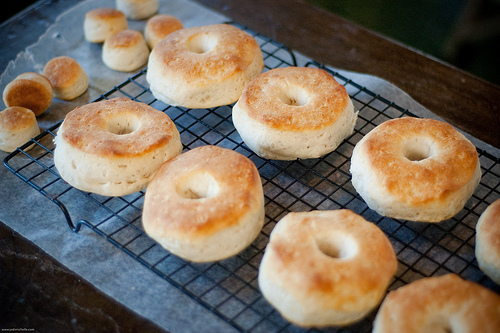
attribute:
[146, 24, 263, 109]
biscuit — brown, plain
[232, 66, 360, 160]
biscuit — brown, plain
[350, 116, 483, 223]
biscuit — brown, plain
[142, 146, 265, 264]
biscuit — brown, plain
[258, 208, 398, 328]
biscuit — brown, plain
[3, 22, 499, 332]
rack — grated, black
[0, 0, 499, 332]
paper — white, wax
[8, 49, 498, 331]
area — black, gray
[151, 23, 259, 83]
top — brown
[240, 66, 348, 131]
top — brown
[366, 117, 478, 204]
top — brown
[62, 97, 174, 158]
top — brown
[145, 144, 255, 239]
top — brown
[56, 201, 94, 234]
leg — stand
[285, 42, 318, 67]
leg — stand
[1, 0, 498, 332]
table — wooden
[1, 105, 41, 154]
ball — brown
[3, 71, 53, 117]
ball — brown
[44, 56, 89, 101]
ball — brown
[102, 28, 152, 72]
ball — brown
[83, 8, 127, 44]
ball — brown